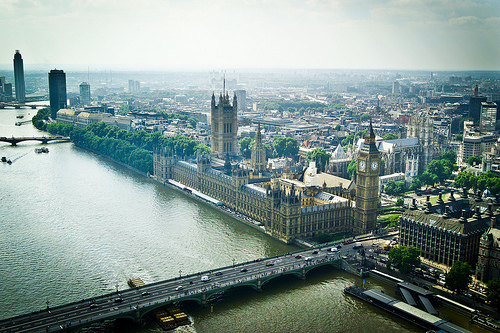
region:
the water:
[82, 210, 221, 310]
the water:
[151, 159, 262, 271]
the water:
[141, 214, 256, 314]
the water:
[100, 169, 172, 263]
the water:
[44, 173, 182, 282]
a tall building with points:
[159, 45, 312, 232]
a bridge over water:
[18, 208, 451, 328]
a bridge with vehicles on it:
[98, 237, 398, 331]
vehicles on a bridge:
[85, 240, 386, 325]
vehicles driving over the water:
[82, 219, 488, 328]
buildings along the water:
[219, 75, 497, 301]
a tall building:
[173, 57, 294, 203]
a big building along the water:
[114, 79, 431, 281]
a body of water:
[37, 172, 162, 264]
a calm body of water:
[50, 185, 177, 280]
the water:
[59, 244, 138, 279]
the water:
[64, 146, 148, 251]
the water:
[34, 194, 116, 255]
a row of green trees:
[63, 122, 162, 174]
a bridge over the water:
[0, 240, 339, 332]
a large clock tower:
[349, 113, 383, 231]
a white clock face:
[368, 158, 383, 172]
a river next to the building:
[0, 99, 497, 331]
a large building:
[140, 69, 392, 249]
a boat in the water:
[33, 144, 53, 155]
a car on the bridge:
[138, 287, 153, 300]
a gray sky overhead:
[0, 0, 499, 75]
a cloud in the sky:
[443, 10, 498, 27]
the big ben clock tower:
[356, 130, 380, 230]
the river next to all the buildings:
[1, 98, 438, 327]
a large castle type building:
[156, 139, 342, 240]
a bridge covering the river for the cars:
[4, 247, 341, 332]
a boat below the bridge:
[126, 280, 186, 328]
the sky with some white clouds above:
[6, 1, 485, 61]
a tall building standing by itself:
[9, 42, 26, 104]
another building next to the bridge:
[383, 176, 498, 313]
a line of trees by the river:
[86, 117, 185, 179]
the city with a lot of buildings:
[283, 62, 457, 175]